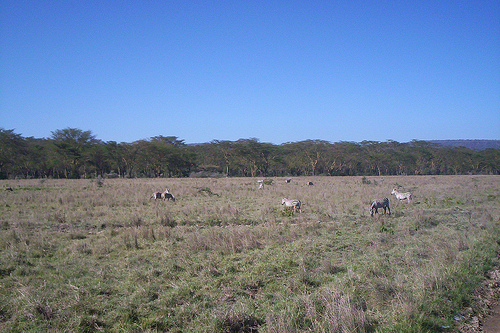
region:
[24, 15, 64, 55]
white clouds in blue sky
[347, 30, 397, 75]
white clouds in blue sky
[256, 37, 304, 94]
white clouds in blue sky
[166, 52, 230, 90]
white clouds in blue sky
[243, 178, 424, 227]
animals grazing in field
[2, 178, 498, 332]
field of shrubs and weeds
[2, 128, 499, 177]
tree line in distance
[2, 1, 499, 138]
sky has no clouds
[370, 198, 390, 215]
horse is eating something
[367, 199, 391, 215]
the horse is gray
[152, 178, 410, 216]
a group of horses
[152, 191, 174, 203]
horse is black and white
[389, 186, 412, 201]
the horse is white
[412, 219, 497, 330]
line of green shrubs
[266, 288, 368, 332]
the weeds are brown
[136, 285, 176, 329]
tall grass on ground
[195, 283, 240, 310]
tall grass on ground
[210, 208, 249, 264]
tall grass on ground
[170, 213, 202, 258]
tall grass on ground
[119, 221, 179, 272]
tall grass on ground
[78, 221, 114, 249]
tall grass on ground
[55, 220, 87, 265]
tall grass on ground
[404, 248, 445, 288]
tall grass on ground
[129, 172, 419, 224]
a group of animals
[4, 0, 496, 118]
a clear blue sky above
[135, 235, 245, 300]
green grass in the field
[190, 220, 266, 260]
died brown grass in the field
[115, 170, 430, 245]
a group of animals grazing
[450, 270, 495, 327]
dirt and gravel on a road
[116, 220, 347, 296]
green and brown grasses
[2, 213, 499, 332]
green and brown grasses in a field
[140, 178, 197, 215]
animals grazing in field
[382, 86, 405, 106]
white clouds in blue sky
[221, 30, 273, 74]
white clouds in blue sky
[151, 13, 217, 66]
white clouds in blue sky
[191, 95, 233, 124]
white clouds in blue sky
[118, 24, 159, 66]
white clouds in blue sky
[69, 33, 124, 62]
white clouds in blue sky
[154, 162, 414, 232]
the animals in the field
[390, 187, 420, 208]
the animal is white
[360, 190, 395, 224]
the animal is gray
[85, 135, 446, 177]
trees in the distance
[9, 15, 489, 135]
the sky is clear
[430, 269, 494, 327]
grass is above the rocks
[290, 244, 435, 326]
hay is in the grass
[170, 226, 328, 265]
the hay is brown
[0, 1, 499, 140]
A solid blue sky.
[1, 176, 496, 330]
A grassy green and brown field.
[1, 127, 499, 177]
A tree line past the field.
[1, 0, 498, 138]
A blue sky past the trees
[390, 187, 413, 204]
The largest grey/white animal.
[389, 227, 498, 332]
Tall green grass along a dirt area.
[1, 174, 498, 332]
A large mostly brown grassy field.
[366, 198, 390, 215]
Grey horse between two white ones.